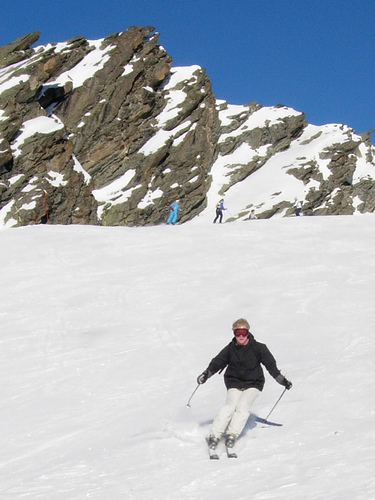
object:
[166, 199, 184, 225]
person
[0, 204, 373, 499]
snow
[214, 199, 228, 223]
person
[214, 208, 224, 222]
pants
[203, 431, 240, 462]
skis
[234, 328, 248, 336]
goggles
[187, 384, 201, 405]
pole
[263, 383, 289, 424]
pole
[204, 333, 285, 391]
black coat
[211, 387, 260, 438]
pair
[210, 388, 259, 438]
pants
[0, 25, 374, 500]
landscape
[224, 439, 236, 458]
ski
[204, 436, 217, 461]
ski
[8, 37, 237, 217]
rocky edge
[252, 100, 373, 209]
rocky edge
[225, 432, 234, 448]
ski boot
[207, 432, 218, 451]
ski boot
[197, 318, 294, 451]
man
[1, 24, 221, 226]
rock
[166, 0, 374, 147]
blue sky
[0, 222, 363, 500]
slope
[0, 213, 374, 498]
area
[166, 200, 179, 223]
ski suit